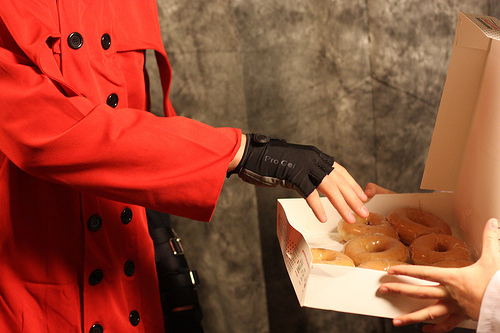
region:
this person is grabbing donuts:
[19, 21, 476, 313]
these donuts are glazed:
[289, 167, 477, 297]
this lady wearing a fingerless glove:
[235, 129, 374, 225]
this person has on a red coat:
[18, 8, 242, 310]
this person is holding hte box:
[378, 215, 494, 320]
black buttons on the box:
[44, 21, 169, 323]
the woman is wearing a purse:
[120, 46, 228, 320]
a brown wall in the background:
[184, 5, 418, 184]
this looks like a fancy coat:
[16, 8, 241, 319]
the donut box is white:
[265, 186, 419, 311]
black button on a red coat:
[86, 266, 106, 288]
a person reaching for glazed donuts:
[0, 0, 498, 332]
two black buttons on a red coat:
[86, 256, 138, 287]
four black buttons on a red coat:
[79, 205, 156, 288]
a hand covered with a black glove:
[232, 131, 372, 225]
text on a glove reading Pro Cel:
[257, 151, 299, 172]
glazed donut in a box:
[304, 242, 354, 267]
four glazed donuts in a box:
[336, 203, 474, 261]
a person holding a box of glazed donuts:
[274, 10, 499, 332]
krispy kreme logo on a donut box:
[473, 12, 498, 31]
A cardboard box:
[272, 10, 497, 328]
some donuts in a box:
[310, 206, 475, 266]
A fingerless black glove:
[225, 126, 330, 192]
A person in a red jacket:
[0, 0, 365, 330]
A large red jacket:
[1, 0, 237, 330]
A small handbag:
[146, 216, 206, 328]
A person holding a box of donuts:
[362, 180, 494, 330]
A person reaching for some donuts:
[0, 0, 366, 325]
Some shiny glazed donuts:
[311, 213, 474, 272]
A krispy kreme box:
[275, 16, 496, 328]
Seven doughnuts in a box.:
[302, 199, 479, 289]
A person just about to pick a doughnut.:
[2, 4, 476, 329]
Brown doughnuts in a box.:
[302, 206, 489, 303]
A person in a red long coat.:
[2, 2, 250, 331]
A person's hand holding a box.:
[377, 205, 494, 328]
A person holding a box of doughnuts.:
[379, 199, 493, 329]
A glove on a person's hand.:
[234, 129, 374, 234]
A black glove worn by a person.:
[237, 122, 374, 231]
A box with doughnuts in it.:
[268, 5, 494, 331]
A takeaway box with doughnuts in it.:
[260, 9, 496, 327]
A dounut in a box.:
[337, 221, 402, 266]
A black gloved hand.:
[242, 123, 370, 226]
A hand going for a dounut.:
[282, 137, 392, 291]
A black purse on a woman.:
[158, 232, 217, 330]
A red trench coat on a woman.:
[10, 5, 254, 329]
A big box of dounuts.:
[275, 192, 414, 322]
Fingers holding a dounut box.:
[377, 263, 473, 324]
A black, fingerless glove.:
[240, 130, 340, 200]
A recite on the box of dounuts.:
[277, 253, 327, 310]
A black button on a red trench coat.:
[57, 27, 94, 62]